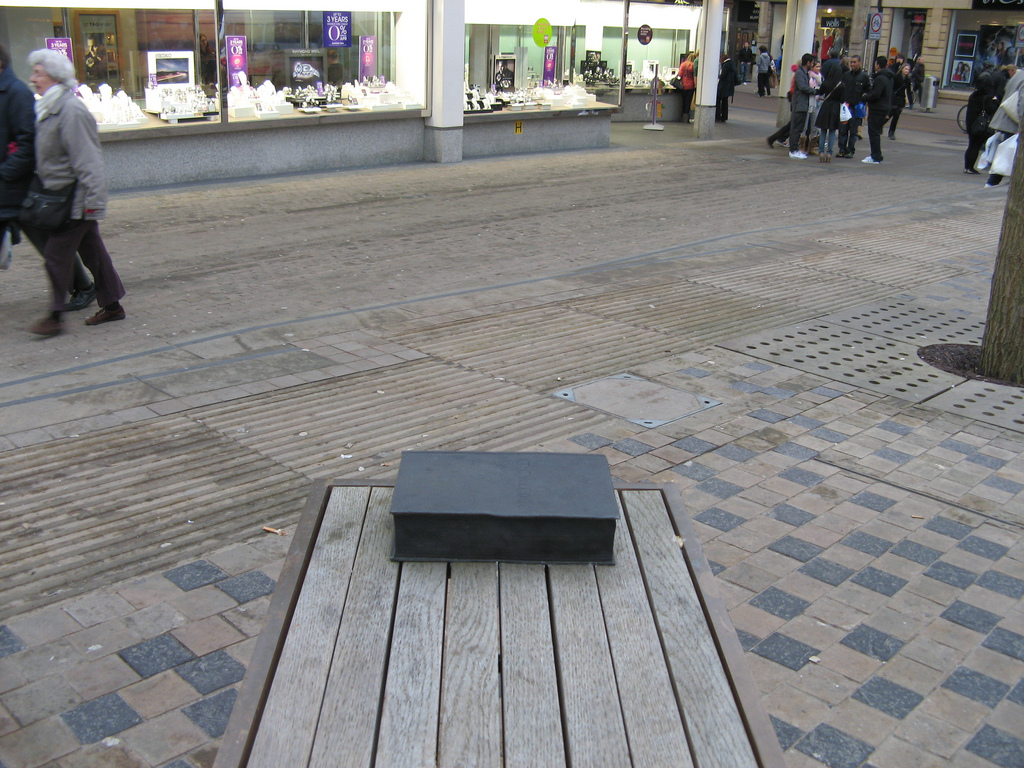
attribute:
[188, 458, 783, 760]
table — wood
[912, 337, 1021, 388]
planter — circular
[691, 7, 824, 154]
pillars — white, grey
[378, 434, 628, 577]
book — black , large 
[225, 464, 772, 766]
plank — wooden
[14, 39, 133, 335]
lady — old 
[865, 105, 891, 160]
jeans — black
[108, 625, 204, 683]
stone — black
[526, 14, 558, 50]
sign — green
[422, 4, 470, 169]
pillar — cement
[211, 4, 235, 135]
divider — metal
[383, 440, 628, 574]
box — back, black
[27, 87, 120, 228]
sweater — grey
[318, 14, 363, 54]
poster — purple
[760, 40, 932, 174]
people — group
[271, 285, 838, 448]
bricks — multicolored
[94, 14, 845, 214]
stores — retail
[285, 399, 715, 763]
door — secret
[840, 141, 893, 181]
shoe — white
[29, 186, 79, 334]
leg — blurry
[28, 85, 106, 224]
coat — goat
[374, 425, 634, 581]
box — black